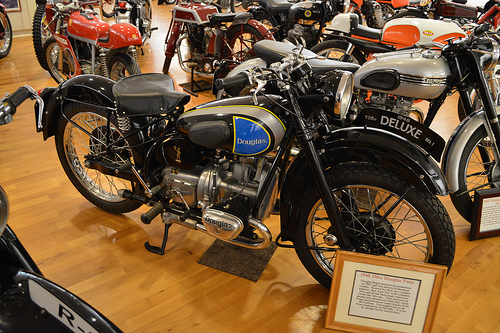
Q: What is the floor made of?
A: Wood.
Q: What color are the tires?
A: Black.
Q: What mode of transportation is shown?
A: Motorcycles.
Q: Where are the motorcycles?
A: Inside a building.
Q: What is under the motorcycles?
A: Floor.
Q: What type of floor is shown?
A: Hardwood.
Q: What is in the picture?
A: Motorcycles.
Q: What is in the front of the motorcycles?
A: A picture frame.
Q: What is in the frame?
A: A certificate.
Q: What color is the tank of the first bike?
A: Blue and silver.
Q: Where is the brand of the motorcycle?
A: Written on the tank.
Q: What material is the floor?
A: Wood.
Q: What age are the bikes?
A: They are classics.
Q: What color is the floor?
A: Brown.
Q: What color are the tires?
A: Black.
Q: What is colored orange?
A: The third bike.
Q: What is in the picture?
A: Motorcycles.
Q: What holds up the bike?
A: Kickstand.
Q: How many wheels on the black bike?
A: 2.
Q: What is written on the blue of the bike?
A: Douglas.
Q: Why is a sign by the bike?
A: About it.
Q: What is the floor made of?
A: Wood.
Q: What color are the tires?
A: Black.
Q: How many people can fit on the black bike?
A: 1.